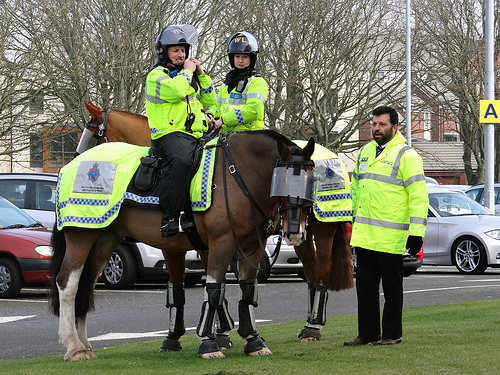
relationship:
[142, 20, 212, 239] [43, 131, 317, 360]
cop rides horse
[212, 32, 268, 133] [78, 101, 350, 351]
cop rides horse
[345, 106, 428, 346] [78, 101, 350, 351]
cop stands next to horse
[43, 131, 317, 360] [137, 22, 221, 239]
horse has cop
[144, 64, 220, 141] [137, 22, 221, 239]
jacket worn by cop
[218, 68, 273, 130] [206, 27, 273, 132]
jacket worn by cop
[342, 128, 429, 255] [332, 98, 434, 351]
jacket worn by cop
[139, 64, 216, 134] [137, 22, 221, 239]
jacket worn by cop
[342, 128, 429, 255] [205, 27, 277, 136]
jacket worn by cop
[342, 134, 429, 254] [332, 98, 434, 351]
jacket worn by cop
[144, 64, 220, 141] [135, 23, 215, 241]
jacket worn by cop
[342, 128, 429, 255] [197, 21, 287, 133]
jacket worn by cop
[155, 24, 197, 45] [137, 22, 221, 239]
helmet worn by cop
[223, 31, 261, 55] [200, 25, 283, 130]
helmet worn by cop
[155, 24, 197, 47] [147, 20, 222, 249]
helmet worn by cop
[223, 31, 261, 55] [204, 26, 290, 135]
helmet worn by cop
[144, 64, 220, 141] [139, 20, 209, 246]
jacket on person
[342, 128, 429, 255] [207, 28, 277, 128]
jacket on person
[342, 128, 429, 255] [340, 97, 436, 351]
jacket on person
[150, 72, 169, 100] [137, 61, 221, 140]
stripe on jacket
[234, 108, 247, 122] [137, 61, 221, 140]
stripe on jacket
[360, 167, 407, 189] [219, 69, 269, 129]
stripe on jacket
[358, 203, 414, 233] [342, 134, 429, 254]
stripe on jacket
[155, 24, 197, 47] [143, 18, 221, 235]
helmet on person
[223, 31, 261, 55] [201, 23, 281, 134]
helmet on person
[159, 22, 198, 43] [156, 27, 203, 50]
visor on helmet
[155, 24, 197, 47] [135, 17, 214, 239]
helmet on person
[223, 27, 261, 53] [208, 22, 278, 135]
helmet on person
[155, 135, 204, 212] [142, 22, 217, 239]
pants on cop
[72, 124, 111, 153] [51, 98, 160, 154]
visor on horse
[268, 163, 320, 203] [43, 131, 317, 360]
visor on horse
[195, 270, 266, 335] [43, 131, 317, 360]
padding on front of horse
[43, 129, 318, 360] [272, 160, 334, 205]
horse wearing visor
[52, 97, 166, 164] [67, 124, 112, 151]
horse wearing visor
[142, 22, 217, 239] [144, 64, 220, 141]
cop wearing jacket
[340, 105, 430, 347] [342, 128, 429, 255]
cop wearing jacket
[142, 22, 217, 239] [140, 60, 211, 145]
cop wearing coat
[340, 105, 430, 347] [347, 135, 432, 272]
cop wearing coat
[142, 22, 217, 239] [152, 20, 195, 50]
cop with helmet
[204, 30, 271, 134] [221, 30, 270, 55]
cop with helmet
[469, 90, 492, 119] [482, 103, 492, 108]
sign with letter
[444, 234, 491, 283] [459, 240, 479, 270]
tire with rim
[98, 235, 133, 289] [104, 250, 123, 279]
tire with rim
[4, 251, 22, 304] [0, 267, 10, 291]
tire with rim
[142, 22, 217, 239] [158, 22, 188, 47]
cop adjusting helmet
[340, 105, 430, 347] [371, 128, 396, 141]
cop with beard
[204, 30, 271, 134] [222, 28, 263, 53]
cop wearing helmet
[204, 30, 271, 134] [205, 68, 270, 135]
cop wearing jacket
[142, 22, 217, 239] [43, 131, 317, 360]
cop on horse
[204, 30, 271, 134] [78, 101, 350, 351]
cop on horse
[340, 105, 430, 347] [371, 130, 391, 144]
cop has beard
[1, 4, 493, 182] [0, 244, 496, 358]
trees behind parking lot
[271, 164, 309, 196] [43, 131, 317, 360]
face guard on horse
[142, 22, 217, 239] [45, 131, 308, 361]
cop adjusting helmet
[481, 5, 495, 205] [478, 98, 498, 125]
pole has sign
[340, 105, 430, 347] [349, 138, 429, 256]
cop wearing raincoat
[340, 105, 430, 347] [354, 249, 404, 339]
cop wearing pants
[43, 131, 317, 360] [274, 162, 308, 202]
horse wearing visor